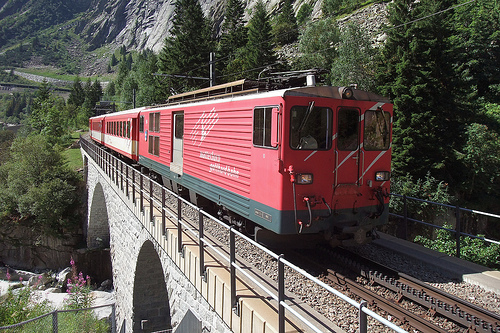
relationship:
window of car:
[247, 108, 286, 145] [89, 75, 393, 245]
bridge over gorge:
[70, 136, 499, 332] [3, 226, 125, 321]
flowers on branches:
[65, 257, 89, 295] [71, 296, 87, 309]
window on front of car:
[335, 109, 359, 150] [89, 75, 393, 245]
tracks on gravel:
[303, 243, 491, 332] [288, 277, 369, 332]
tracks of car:
[303, 243, 491, 332] [89, 75, 393, 245]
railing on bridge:
[98, 147, 403, 332] [70, 136, 499, 332]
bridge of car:
[70, 136, 499, 332] [89, 75, 393, 245]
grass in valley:
[57, 125, 84, 171] [2, 5, 91, 200]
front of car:
[281, 88, 392, 243] [89, 75, 393, 245]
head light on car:
[293, 169, 319, 190] [89, 75, 393, 245]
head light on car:
[373, 169, 391, 183] [89, 75, 393, 245]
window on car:
[335, 109, 359, 150] [89, 75, 393, 245]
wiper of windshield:
[290, 102, 314, 148] [290, 100, 334, 154]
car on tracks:
[89, 75, 393, 245] [303, 243, 491, 332]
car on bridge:
[89, 75, 393, 245] [70, 136, 499, 332]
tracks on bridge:
[303, 243, 491, 332] [70, 136, 499, 332]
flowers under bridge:
[65, 257, 89, 295] [70, 136, 499, 332]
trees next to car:
[376, 0, 499, 207] [89, 75, 393, 245]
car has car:
[89, 75, 393, 245] [89, 75, 393, 245]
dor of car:
[332, 104, 368, 190] [89, 75, 393, 245]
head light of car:
[296, 173, 314, 185] [89, 75, 393, 245]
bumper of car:
[326, 223, 380, 247] [89, 75, 393, 245]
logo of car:
[188, 114, 220, 149] [89, 75, 393, 245]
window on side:
[247, 108, 286, 145] [142, 95, 282, 232]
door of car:
[168, 110, 191, 174] [89, 75, 393, 245]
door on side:
[168, 110, 191, 174] [142, 95, 282, 232]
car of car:
[131, 76, 391, 244] [89, 75, 393, 245]